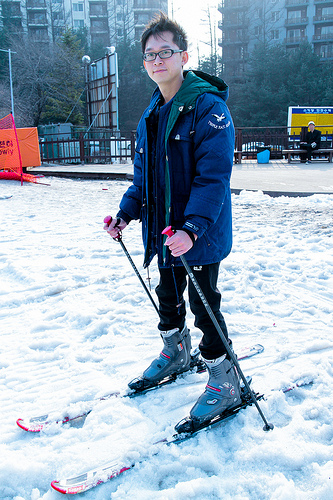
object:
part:
[156, 67, 238, 270]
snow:
[0, 166, 332, 497]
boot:
[188, 345, 244, 423]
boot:
[141, 323, 193, 383]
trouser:
[155, 257, 230, 362]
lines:
[53, 277, 104, 294]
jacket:
[114, 66, 238, 273]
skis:
[49, 355, 314, 496]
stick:
[160, 222, 276, 434]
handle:
[160, 224, 175, 239]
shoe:
[190, 352, 244, 426]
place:
[0, 0, 333, 500]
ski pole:
[101, 209, 163, 325]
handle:
[103, 214, 121, 240]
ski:
[15, 335, 264, 437]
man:
[299, 120, 322, 166]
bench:
[281, 131, 333, 164]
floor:
[0, 0, 169, 20]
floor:
[0, 0, 167, 42]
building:
[0, 0, 170, 155]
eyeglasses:
[139, 47, 188, 64]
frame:
[141, 47, 187, 62]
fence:
[39, 121, 333, 164]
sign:
[84, 49, 120, 138]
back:
[81, 52, 120, 136]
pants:
[154, 261, 232, 361]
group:
[0, 13, 97, 131]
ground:
[0, 144, 333, 500]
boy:
[106, 9, 247, 427]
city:
[0, 0, 333, 197]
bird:
[211, 112, 226, 123]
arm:
[163, 94, 235, 258]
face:
[142, 26, 183, 85]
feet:
[189, 366, 244, 427]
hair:
[140, 17, 189, 51]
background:
[0, 0, 333, 201]